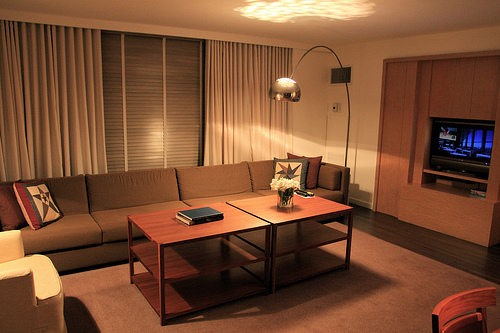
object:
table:
[127, 192, 356, 329]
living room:
[0, 0, 497, 330]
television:
[423, 116, 494, 177]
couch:
[0, 157, 348, 273]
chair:
[0, 229, 65, 331]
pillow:
[14, 179, 66, 230]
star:
[34, 186, 60, 219]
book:
[176, 206, 225, 228]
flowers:
[269, 174, 297, 191]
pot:
[278, 189, 296, 209]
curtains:
[202, 39, 294, 162]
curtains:
[0, 21, 109, 185]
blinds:
[104, 38, 198, 166]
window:
[1, 27, 298, 184]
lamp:
[270, 46, 350, 167]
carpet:
[73, 271, 450, 332]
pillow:
[285, 151, 323, 189]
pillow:
[273, 159, 306, 188]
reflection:
[238, 0, 375, 26]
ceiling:
[0, 0, 499, 47]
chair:
[431, 287, 500, 332]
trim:
[17, 181, 39, 233]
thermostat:
[331, 103, 339, 113]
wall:
[371, 28, 498, 102]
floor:
[341, 201, 500, 286]